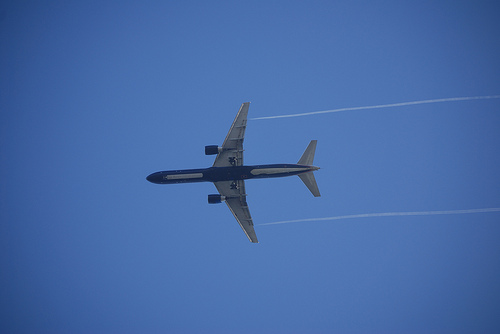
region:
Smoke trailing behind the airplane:
[246, 94, 498, 121]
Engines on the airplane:
[203, 142, 224, 204]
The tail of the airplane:
[297, 139, 322, 196]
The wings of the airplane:
[214, 102, 257, 242]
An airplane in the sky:
[147, 101, 320, 241]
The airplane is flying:
[146, 102, 323, 243]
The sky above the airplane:
[1, 1, 498, 333]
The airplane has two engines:
[206, 144, 222, 205]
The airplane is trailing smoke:
[147, 102, 320, 244]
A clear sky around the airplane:
[0, 1, 498, 333]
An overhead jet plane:
[35, 28, 497, 331]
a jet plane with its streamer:
[69, 55, 498, 318]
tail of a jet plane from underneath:
[285, 125, 332, 223]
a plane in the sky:
[90, 92, 440, 299]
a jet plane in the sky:
[85, 90, 449, 279]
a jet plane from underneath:
[95, 95, 489, 263]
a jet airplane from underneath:
[57, 93, 470, 265]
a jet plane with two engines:
[61, 91, 443, 272]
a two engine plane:
[52, 93, 497, 253]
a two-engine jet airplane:
[57, 91, 498, 267]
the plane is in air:
[136, 131, 326, 218]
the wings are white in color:
[208, 116, 277, 238]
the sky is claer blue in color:
[304, 47, 421, 94]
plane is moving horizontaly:
[173, 115, 335, 228]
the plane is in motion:
[144, 117, 311, 229]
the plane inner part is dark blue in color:
[147, 153, 346, 207]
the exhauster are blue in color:
[203, 142, 251, 157]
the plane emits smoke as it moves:
[338, 92, 463, 127]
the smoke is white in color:
[376, 84, 467, 133]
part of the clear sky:
[27, 80, 114, 138]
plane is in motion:
[158, 120, 336, 288]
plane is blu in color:
[151, 121, 276, 218]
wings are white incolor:
[203, 112, 263, 234]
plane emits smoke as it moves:
[221, 94, 353, 251]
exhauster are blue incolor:
[195, 139, 232, 153]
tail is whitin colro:
[304, 133, 327, 199]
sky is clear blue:
[50, 141, 91, 221]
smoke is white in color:
[258, 98, 365, 131]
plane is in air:
[146, 124, 311, 240]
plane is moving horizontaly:
[126, 146, 376, 287]